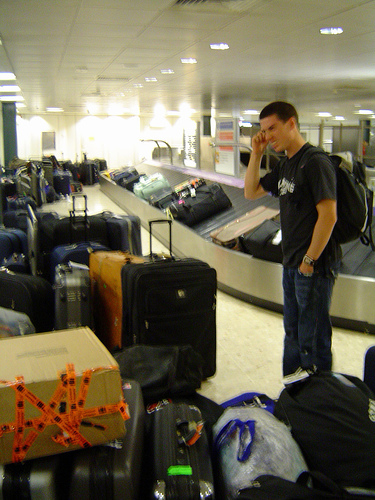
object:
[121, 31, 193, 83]
ceiling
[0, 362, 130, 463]
tape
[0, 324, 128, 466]
box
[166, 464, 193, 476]
tag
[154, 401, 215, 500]
suitcase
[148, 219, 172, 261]
handle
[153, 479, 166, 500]
tips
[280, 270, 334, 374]
jeans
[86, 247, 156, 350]
revolving belt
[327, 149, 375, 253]
back pack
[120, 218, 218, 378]
bag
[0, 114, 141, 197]
windows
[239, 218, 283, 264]
baggage claim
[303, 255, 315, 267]
wrist watch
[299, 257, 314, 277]
hand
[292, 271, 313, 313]
pocket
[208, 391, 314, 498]
bag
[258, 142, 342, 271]
shirt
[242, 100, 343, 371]
man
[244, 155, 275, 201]
arm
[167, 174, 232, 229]
luggage